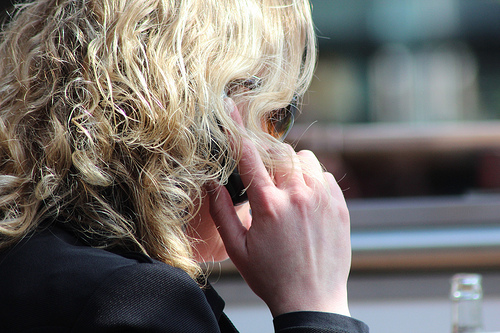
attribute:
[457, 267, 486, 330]
bottle — clear, small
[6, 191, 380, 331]
shirt — dark colored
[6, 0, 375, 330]
woman — blonde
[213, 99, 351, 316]
skin — pale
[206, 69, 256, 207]
phone — cellular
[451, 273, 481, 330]
bottle — glass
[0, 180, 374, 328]
jacket — black, suit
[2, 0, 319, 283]
hair — curly, blonde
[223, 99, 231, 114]
nail — finger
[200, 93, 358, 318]
hand — white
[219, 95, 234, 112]
nail — finger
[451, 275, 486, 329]
bottle — glass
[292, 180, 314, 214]
knuckle — middle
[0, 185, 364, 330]
coat — black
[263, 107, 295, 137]
sunglasses — brown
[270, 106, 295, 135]
sunglasses — brown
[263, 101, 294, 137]
sunglasses — brown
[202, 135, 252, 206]
cellphone — black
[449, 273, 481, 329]
bottle top — clear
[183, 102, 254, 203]
phone — Black 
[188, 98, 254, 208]
phone — black , small 